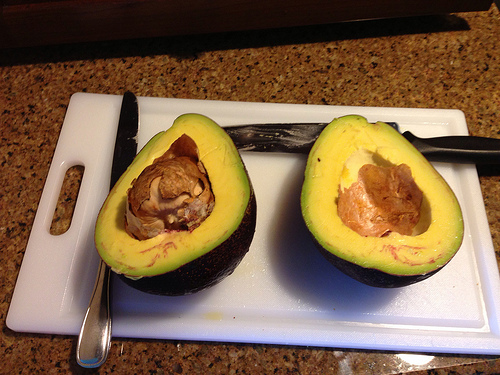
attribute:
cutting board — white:
[6, 91, 499, 356]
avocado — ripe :
[111, 120, 488, 291]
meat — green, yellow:
[122, 128, 219, 231]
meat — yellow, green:
[331, 157, 427, 240]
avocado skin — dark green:
[119, 138, 257, 297]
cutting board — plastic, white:
[23, 80, 498, 328]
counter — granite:
[3, 11, 498, 373]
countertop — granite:
[7, 10, 497, 372]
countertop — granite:
[18, 49, 498, 106]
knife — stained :
[217, 102, 346, 164]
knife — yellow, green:
[84, 86, 136, 373]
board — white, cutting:
[50, 92, 497, 347]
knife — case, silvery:
[72, 81, 139, 371]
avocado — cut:
[86, 110, 468, 290]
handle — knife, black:
[404, 129, 499, 164]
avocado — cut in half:
[166, 118, 268, 278]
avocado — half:
[109, 112, 256, 294]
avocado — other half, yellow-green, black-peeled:
[293, 110, 465, 288]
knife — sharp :
[226, 106, 498, 175]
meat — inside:
[298, 115, 467, 287]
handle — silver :
[73, 260, 123, 372]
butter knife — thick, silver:
[52, 79, 139, 365]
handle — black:
[402, 127, 499, 166]